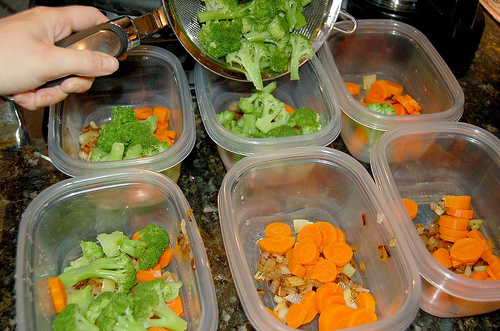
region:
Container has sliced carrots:
[224, 149, 414, 329]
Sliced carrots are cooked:
[258, 212, 376, 329]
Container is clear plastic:
[211, 151, 418, 329]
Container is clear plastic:
[14, 175, 219, 329]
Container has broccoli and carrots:
[46, 212, 188, 326]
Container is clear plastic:
[381, 123, 495, 320]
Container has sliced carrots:
[395, 150, 499, 277]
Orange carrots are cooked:
[407, 166, 498, 293]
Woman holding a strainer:
[4, 0, 391, 87]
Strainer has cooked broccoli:
[153, 1, 377, 89]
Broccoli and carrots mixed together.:
[52, 217, 170, 277]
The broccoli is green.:
[67, 220, 166, 274]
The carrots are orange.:
[257, 208, 357, 279]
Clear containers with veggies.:
[33, 141, 496, 328]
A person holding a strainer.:
[5, 6, 137, 107]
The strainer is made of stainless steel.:
[142, 0, 342, 90]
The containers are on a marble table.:
[0, 60, 489, 312]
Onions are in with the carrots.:
[254, 203, 371, 313]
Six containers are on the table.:
[31, 16, 497, 325]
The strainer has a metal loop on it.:
[280, 0, 368, 54]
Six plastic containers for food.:
[98, 5, 490, 323]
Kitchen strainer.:
[115, 1, 361, 79]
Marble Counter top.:
[174, 153, 216, 208]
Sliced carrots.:
[292, 212, 342, 283]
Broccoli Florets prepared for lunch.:
[91, 105, 154, 156]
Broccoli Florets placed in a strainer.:
[162, 1, 352, 83]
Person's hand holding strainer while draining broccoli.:
[7, 0, 355, 96]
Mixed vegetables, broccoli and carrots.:
[34, 227, 196, 327]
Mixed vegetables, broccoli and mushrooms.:
[255, 217, 386, 311]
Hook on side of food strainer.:
[324, 2, 359, 38]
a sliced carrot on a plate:
[258, 233, 295, 252]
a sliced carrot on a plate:
[327, 237, 349, 267]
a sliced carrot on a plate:
[316, 260, 337, 287]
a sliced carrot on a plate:
[291, 300, 306, 327]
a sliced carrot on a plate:
[297, 230, 312, 262]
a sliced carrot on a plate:
[298, 222, 314, 244]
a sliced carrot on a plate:
[285, 301, 299, 319]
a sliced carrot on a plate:
[451, 227, 478, 267]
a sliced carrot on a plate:
[443, 194, 472, 213]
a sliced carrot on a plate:
[436, 212, 463, 233]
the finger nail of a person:
[97, 50, 122, 75]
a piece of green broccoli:
[109, 221, 176, 272]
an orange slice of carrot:
[321, 239, 356, 270]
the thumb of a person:
[40, 39, 122, 79]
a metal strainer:
[160, 0, 359, 90]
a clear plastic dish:
[213, 140, 433, 328]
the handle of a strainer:
[0, 11, 140, 113]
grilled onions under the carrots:
[251, 256, 296, 311]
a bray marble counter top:
[0, 0, 498, 328]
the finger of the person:
[54, 7, 116, 102]